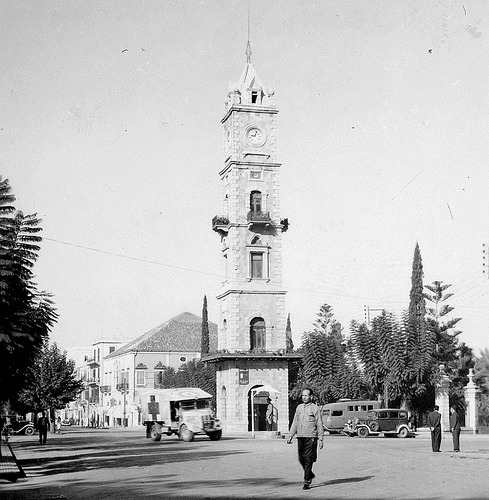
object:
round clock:
[244, 124, 265, 148]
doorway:
[247, 384, 277, 432]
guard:
[263, 393, 273, 433]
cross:
[145, 393, 159, 422]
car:
[342, 406, 414, 441]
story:
[202, 354, 301, 435]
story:
[216, 290, 288, 353]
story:
[211, 220, 289, 292]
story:
[219, 164, 283, 222]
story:
[222, 105, 278, 161]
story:
[217, 61, 281, 109]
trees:
[197, 294, 210, 352]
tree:
[17, 339, 88, 434]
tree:
[407, 241, 426, 325]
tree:
[469, 345, 489, 396]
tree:
[419, 277, 467, 364]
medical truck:
[137, 384, 223, 442]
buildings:
[99, 307, 219, 425]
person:
[287, 387, 325, 490]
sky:
[2, 0, 488, 373]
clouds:
[0, 0, 488, 368]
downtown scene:
[0, 0, 487, 500]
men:
[425, 403, 441, 455]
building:
[209, 0, 290, 440]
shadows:
[303, 472, 375, 487]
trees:
[0, 172, 61, 406]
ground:
[4, 420, 488, 499]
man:
[447, 404, 463, 452]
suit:
[448, 414, 462, 450]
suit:
[427, 411, 441, 449]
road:
[0, 425, 487, 496]